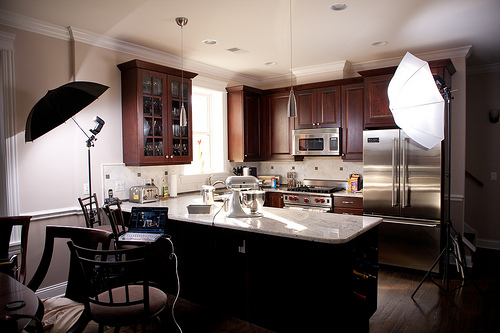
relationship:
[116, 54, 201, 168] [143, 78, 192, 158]
cabinet fronted by glass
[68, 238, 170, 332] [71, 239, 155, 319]
chair with back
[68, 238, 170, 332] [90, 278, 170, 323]
chair with seat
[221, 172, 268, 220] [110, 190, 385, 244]
mixer on counter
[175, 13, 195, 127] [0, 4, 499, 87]
light hanging from ceiling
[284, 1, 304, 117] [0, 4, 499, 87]
light hanging from ceiling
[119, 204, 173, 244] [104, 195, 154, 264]
laptop on chair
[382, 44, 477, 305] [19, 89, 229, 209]
umbrellag reflecting light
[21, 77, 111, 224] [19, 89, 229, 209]
umbrella diffusing light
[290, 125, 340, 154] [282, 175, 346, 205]
microwave above stove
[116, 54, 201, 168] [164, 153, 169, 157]
cabinet with knob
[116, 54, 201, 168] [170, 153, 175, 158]
cabinet with knob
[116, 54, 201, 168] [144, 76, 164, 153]
cabinet has window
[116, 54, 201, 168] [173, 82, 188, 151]
cabinet has window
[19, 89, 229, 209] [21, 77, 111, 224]
light has umbrella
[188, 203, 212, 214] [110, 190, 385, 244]
pan on counter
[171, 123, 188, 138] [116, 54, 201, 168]
glasswear in cabinet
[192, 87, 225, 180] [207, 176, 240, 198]
view above sink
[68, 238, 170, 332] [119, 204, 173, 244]
chair and laptop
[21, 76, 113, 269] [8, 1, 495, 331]
source for photography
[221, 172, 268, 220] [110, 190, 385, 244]
mixer on counter top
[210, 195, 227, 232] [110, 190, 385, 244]
cord on counter top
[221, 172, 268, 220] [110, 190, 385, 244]
mixer on countertop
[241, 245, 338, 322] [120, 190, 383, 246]
cabinet with countertops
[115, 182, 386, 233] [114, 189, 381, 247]
countertop with granite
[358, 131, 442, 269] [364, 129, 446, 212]
refrigerator has doors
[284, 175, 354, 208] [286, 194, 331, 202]
range with dials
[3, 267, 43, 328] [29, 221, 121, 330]
table with chair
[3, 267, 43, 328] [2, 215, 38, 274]
table with chair